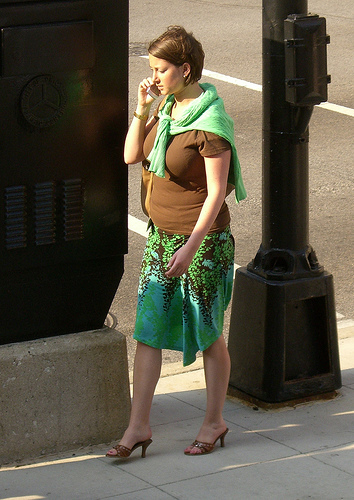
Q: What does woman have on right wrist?
A: A watch.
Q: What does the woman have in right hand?
A: A cell phone.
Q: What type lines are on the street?
A: White lines.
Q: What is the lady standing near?
A: A light post.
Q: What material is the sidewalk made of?
A: Concrete.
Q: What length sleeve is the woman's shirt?
A: A short sleeved shirt.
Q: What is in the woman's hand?
A: Cell Phone.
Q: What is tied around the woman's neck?
A: Sweater.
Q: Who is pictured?
A: A woman.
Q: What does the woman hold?
A: A cell phone.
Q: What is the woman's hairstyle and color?
A: Brown and short.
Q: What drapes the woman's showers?
A: A green sweater.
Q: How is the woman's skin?
A: Caucasian.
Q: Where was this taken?
A: A city street.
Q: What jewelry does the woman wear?
A: A watch and earrings.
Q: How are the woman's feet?
A: Painted red.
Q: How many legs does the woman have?
A: Two.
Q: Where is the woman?
A: On the sidewalk.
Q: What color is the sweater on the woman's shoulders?
A: Green.